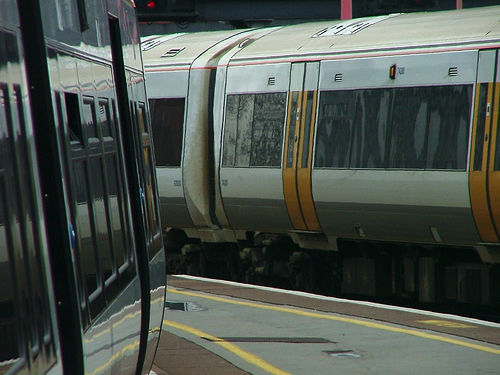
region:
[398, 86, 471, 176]
Part of a glass window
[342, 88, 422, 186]
Part of a glass window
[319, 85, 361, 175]
Part of a glass window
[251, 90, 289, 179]
Part of a glass window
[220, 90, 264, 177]
Part of a glass window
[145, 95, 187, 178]
Part of a glass window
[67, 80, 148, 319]
Part of a glass window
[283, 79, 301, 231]
yellow door on train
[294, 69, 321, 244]
yellow door on train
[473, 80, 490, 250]
yellow door on train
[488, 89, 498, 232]
yellow door on train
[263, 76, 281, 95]
small vent on train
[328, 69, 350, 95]
small vent on train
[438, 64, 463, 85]
small vent on train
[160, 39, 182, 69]
small vent on train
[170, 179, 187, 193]
small vent on train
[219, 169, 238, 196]
small vent on train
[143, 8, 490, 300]
a grey train car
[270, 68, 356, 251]
yellow doors on train car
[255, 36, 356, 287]
double doors on train car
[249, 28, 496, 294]
2 sets of doors on train car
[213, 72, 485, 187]
a row of windows on car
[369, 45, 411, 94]
yellow light on train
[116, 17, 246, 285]
second train car on track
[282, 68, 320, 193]
window panel on doors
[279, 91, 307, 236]
a door on the side of a train.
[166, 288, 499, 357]
a long yellow painted line on a walkway.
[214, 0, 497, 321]
a train car sitting on train tracks.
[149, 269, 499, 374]
a walkway between two trains.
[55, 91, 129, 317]
a set of windows on the side of a train.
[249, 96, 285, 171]
a window on the side of a train.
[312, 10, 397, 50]
an indentification mark on the top of a train.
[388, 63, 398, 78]
a light on the side of a train.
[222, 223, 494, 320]
the under carriage on a train.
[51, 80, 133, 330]
a large set of windows.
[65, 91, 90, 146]
small window on train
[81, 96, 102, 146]
small window on train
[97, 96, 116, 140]
small window on train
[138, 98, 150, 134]
small window on train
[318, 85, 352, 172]
small window on train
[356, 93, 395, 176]
small window on train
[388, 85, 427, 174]
small window on train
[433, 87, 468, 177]
small window on train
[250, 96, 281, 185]
small window on train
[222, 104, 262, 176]
small window on train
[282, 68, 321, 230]
long yellow bus doors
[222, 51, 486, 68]
blue and red stripes on bus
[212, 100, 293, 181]
dirty black windows on bus